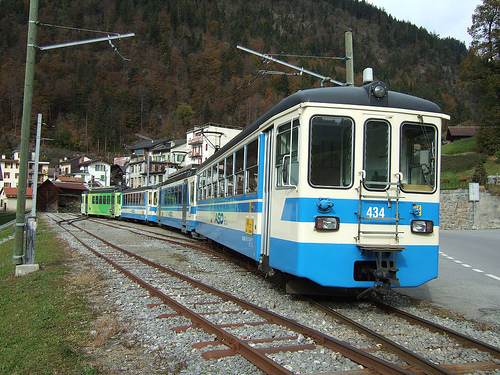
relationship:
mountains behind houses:
[235, 6, 464, 106] [57, 101, 224, 188]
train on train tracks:
[154, 112, 439, 283] [110, 203, 267, 373]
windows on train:
[154, 161, 264, 216] [154, 112, 439, 283]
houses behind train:
[57, 101, 224, 188] [154, 112, 439, 283]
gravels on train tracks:
[111, 244, 209, 281] [110, 203, 267, 373]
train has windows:
[154, 112, 439, 283] [154, 161, 264, 216]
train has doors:
[154, 112, 439, 283] [156, 116, 306, 281]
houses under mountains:
[57, 101, 224, 188] [235, 6, 464, 106]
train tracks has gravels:
[110, 203, 267, 373] [111, 244, 209, 281]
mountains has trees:
[235, 6, 464, 106] [96, 70, 224, 111]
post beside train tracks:
[13, 20, 45, 276] [110, 203, 267, 373]